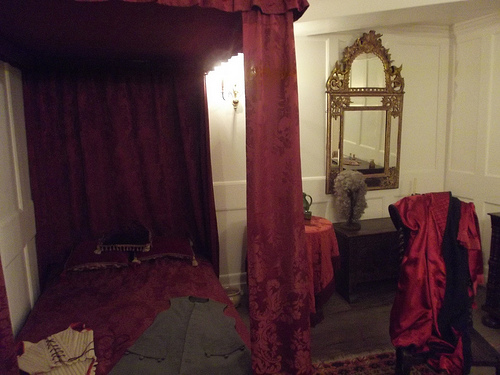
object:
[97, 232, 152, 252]
pillow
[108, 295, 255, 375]
clothing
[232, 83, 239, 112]
sconce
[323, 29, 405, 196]
mirror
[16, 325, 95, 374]
clothing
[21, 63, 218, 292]
drapery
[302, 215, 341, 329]
table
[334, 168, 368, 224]
wig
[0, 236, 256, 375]
bed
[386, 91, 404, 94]
gold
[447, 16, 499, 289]
wall